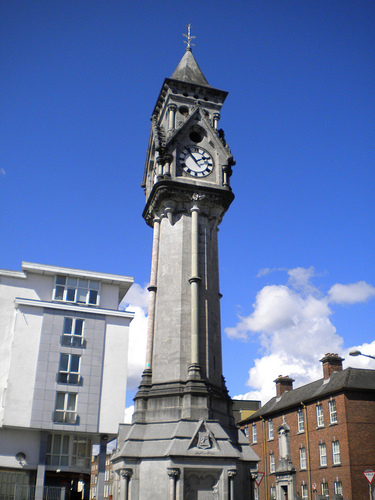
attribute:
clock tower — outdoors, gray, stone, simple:
[150, 30, 268, 387]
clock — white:
[163, 134, 223, 176]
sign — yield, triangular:
[348, 466, 374, 491]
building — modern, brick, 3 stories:
[8, 271, 107, 481]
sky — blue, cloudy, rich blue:
[268, 23, 293, 28]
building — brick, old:
[240, 397, 361, 492]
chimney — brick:
[312, 347, 358, 389]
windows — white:
[310, 402, 348, 434]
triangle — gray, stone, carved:
[180, 418, 233, 458]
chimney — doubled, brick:
[269, 356, 301, 396]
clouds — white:
[225, 267, 352, 338]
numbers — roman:
[193, 142, 205, 156]